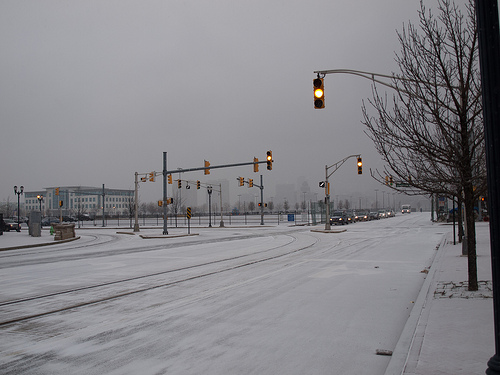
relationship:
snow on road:
[296, 276, 408, 336] [0, 215, 500, 375]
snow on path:
[0, 215, 497, 375] [388, 224, 499, 372]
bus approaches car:
[401, 201, 413, 214] [328, 210, 348, 226]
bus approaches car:
[401, 201, 413, 214] [344, 212, 356, 224]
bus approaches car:
[401, 201, 413, 214] [355, 208, 369, 221]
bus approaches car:
[401, 201, 413, 214] [370, 212, 380, 220]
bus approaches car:
[401, 201, 413, 214] [378, 208, 390, 219]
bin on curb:
[50, 222, 82, 242] [2, 226, 79, 248]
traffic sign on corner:
[183, 207, 193, 233] [136, 229, 196, 239]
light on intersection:
[313, 78, 326, 109] [4, 220, 494, 270]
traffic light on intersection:
[354, 156, 362, 174] [4, 220, 494, 270]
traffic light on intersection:
[266, 150, 272, 169] [4, 220, 494, 270]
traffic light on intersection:
[202, 161, 209, 174] [4, 220, 494, 270]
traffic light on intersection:
[165, 172, 174, 184] [4, 220, 494, 270]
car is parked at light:
[307, 190, 377, 241] [293, 63, 334, 110]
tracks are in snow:
[44, 210, 277, 370] [4, 210, 497, 347]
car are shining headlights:
[329, 210, 348, 225] [329, 217, 354, 224]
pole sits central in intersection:
[308, 155, 352, 217] [179, 193, 352, 279]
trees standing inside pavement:
[428, 43, 498, 301] [417, 243, 466, 316]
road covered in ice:
[0, 215, 500, 375] [316, 252, 345, 277]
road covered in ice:
[175, 214, 229, 242] [316, 252, 345, 277]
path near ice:
[388, 224, 499, 372] [31, 324, 84, 343]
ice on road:
[31, 324, 84, 343] [54, 200, 456, 363]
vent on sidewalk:
[370, 341, 398, 366] [429, 257, 473, 372]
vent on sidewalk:
[376, 349, 392, 356] [16, 215, 103, 255]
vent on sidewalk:
[328, 207, 374, 227] [276, 207, 334, 227]